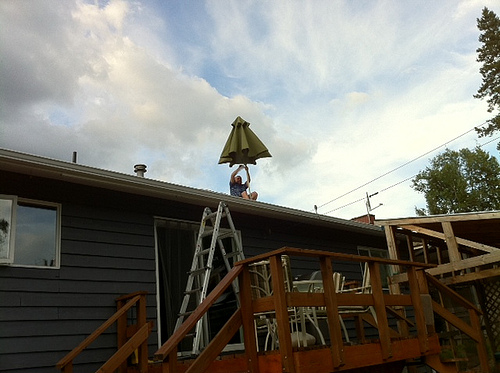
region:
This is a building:
[11, 133, 481, 365]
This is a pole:
[265, 246, 307, 370]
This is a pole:
[314, 233, 345, 368]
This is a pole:
[368, 243, 400, 371]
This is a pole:
[437, 195, 464, 283]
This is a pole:
[381, 206, 413, 290]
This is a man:
[225, 155, 256, 215]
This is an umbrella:
[211, 102, 288, 214]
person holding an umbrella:
[218, 115, 272, 200]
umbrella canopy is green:
[216, 115, 270, 164]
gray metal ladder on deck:
[171, 200, 263, 354]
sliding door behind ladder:
[156, 216, 248, 352]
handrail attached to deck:
[56, 263, 253, 371]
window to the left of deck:
[0, 195, 61, 267]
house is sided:
[1, 147, 434, 372]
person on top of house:
[228, 163, 258, 197]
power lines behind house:
[296, 110, 498, 213]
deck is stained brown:
[55, 243, 488, 372]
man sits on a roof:
[163, 160, 310, 222]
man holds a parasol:
[211, 106, 282, 216]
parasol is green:
[211, 108, 271, 165]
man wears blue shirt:
[220, 159, 265, 207]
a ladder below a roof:
[145, 174, 281, 354]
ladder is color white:
[169, 192, 296, 353]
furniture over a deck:
[219, 248, 417, 371]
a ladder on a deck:
[151, 193, 409, 370]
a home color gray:
[0, 151, 396, 357]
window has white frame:
[0, 188, 68, 269]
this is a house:
[78, 200, 140, 269]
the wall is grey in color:
[75, 210, 140, 285]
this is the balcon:
[303, 253, 410, 357]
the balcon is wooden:
[321, 254, 433, 365]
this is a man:
[218, 165, 260, 197]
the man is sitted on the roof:
[218, 164, 260, 204]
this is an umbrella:
[218, 118, 261, 156]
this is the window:
[9, 202, 54, 264]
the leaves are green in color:
[430, 159, 477, 208]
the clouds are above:
[99, 73, 187, 135]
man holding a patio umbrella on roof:
[212, 95, 269, 205]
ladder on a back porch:
[177, 192, 266, 362]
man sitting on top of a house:
[226, 164, 263, 199]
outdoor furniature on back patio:
[249, 251, 394, 343]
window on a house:
[0, 195, 75, 270]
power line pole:
[350, 178, 384, 216]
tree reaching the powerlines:
[397, 142, 497, 211]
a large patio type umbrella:
[221, 107, 266, 169]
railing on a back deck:
[235, 249, 482, 372]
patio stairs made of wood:
[132, 337, 190, 372]